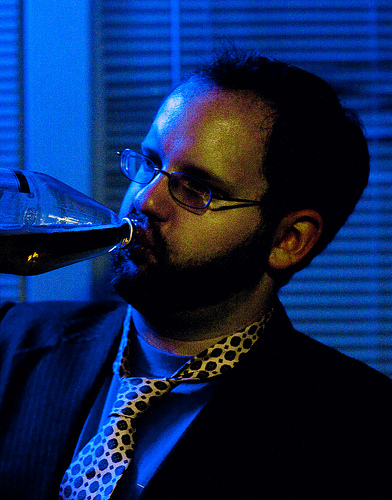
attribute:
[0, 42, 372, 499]
man — drinking, color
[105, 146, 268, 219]
glasses — metal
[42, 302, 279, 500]
tie — yellow, loosened, black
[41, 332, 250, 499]
shirt — blue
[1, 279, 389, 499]
jacket — exsisting, striped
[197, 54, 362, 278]
hair — dark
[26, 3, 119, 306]
wall — exsisting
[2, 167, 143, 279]
bottle — clear, dark, tilted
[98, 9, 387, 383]
blind — exsisting, blue, covering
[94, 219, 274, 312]
beard — scruffy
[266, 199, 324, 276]
ear — exposed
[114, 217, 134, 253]
ring — golden